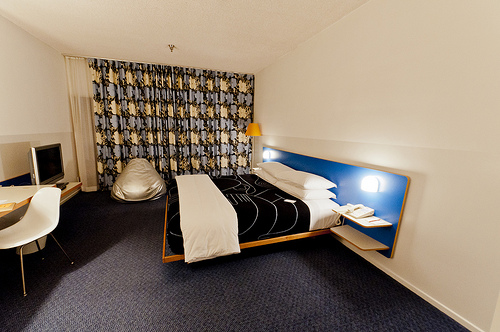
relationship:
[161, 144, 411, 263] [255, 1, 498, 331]
bed attached to wall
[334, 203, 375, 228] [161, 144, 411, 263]
phone next to bed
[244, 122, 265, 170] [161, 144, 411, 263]
lamp next to bed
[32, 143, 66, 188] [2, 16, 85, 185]
television against wall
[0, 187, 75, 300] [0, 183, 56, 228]
chair next to desk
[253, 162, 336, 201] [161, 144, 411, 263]
pillows on bed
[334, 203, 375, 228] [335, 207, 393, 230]
phone on shelf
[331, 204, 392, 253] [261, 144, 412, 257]
shelves on headboard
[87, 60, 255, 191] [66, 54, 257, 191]
curtain on a window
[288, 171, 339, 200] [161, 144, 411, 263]
pillows on bed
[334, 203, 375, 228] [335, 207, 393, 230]
phone on a shelf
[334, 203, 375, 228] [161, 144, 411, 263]
phone beside bed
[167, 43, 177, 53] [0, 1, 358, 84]
sprinkler on ceiling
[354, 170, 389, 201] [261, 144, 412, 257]
light on headboard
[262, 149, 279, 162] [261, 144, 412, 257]
light on headboard